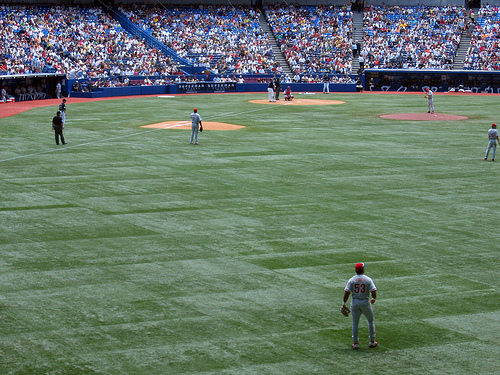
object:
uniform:
[341, 274, 376, 344]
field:
[90, 142, 255, 295]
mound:
[377, 110, 469, 123]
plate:
[246, 98, 346, 108]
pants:
[425, 96, 436, 115]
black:
[50, 112, 72, 145]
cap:
[352, 260, 367, 273]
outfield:
[0, 0, 495, 106]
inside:
[0, 72, 497, 375]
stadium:
[0, 0, 499, 374]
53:
[353, 280, 366, 296]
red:
[354, 259, 366, 271]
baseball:
[0, 0, 499, 375]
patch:
[0, 206, 161, 245]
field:
[5, 171, 470, 375]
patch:
[107, 252, 264, 280]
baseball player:
[340, 262, 377, 350]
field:
[0, 88, 499, 373]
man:
[51, 112, 66, 148]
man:
[338, 258, 380, 349]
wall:
[64, 81, 364, 100]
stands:
[63, 71, 363, 97]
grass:
[0, 91, 499, 374]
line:
[0, 100, 297, 162]